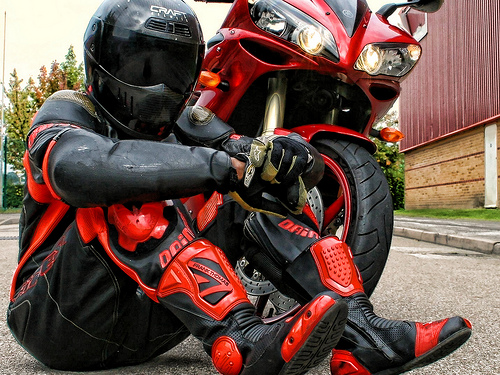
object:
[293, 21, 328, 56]
light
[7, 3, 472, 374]
bike rider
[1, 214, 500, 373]
pavement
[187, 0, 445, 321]
motorcycle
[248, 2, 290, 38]
headlight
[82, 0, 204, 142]
helmet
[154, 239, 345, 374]
boots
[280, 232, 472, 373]
boots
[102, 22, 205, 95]
goggles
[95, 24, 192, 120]
face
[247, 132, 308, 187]
glove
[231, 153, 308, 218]
glove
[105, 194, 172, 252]
knee pad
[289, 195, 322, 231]
knee pad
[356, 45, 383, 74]
headlight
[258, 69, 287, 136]
bar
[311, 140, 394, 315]
tire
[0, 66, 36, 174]
tree